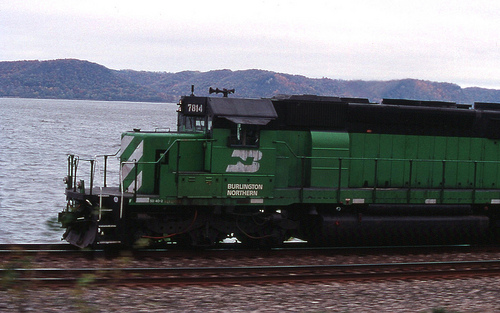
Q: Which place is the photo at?
A: It is at the lake.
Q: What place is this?
A: It is a lake.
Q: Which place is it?
A: It is a lake.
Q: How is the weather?
A: It is cloudy.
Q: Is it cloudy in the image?
A: Yes, it is cloudy.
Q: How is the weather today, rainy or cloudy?
A: It is cloudy.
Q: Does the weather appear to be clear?
A: No, it is cloudy.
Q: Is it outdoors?
A: Yes, it is outdoors.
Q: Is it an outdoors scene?
A: Yes, it is outdoors.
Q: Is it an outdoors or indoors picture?
A: It is outdoors.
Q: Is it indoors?
A: No, it is outdoors.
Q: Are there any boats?
A: No, there are no boats.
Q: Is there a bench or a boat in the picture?
A: No, there are no boats or benches.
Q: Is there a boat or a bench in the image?
A: No, there are no boats or benches.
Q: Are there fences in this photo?
A: No, there are no fences.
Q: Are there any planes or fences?
A: No, there are no fences or planes.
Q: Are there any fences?
A: No, there are no fences.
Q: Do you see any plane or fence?
A: No, there are no fences or airplanes.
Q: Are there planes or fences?
A: No, there are no fences or planes.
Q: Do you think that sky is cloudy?
A: Yes, the sky is cloudy.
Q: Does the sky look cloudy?
A: Yes, the sky is cloudy.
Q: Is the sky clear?
A: No, the sky is cloudy.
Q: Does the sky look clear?
A: No, the sky is cloudy.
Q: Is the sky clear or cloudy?
A: The sky is cloudy.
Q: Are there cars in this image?
A: No, there are no cars.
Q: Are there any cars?
A: No, there are no cars.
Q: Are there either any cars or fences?
A: No, there are no cars or fences.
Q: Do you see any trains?
A: Yes, there is a train.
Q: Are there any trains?
A: Yes, there is a train.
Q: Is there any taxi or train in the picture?
A: Yes, there is a train.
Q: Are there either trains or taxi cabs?
A: Yes, there is a train.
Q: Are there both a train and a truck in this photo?
A: No, there is a train but no trucks.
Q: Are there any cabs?
A: No, there are no cabs.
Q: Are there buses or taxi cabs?
A: No, there are no taxi cabs or buses.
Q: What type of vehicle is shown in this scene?
A: The vehicle is a train.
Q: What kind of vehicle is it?
A: The vehicle is a train.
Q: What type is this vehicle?
A: That is a train.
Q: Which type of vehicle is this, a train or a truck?
A: That is a train.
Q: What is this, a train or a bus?
A: This is a train.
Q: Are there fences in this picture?
A: No, there are no fences.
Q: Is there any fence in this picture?
A: No, there are no fences.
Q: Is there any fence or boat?
A: No, there are no fences or boats.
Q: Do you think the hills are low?
A: Yes, the hills are low.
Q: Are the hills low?
A: Yes, the hills are low.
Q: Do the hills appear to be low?
A: Yes, the hills are low.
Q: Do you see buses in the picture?
A: No, there are no buses.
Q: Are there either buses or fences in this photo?
A: No, there are no buses or fences.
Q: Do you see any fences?
A: No, there are no fences.